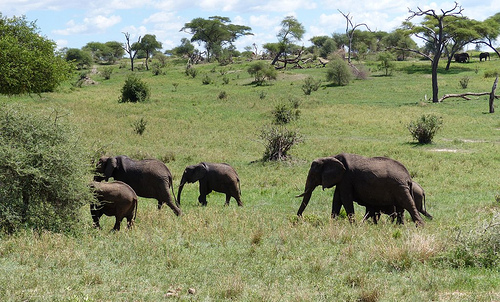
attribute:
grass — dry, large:
[3, 59, 499, 300]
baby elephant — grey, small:
[175, 163, 244, 205]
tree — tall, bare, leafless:
[401, 6, 467, 105]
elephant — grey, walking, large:
[297, 153, 422, 227]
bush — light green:
[1, 105, 86, 239]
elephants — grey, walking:
[83, 156, 243, 230]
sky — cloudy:
[0, 0, 500, 50]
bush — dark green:
[0, 14, 61, 93]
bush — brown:
[260, 127, 296, 162]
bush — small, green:
[119, 73, 150, 104]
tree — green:
[181, 16, 253, 67]